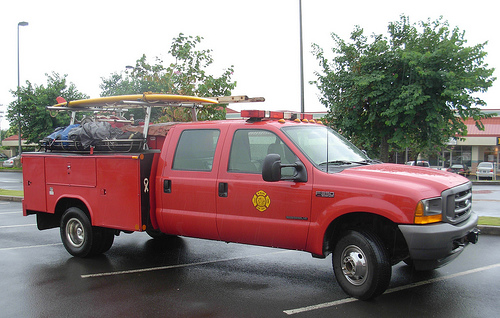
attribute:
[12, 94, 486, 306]
truck — red, parking lot, big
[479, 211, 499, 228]
strip — green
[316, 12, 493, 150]
tree — small, green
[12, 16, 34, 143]
pole — tall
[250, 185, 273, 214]
insignia — yellow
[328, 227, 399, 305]
tire — rubber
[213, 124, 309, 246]
door — red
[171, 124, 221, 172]
window — glass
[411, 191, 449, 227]
headlight — orange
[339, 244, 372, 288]
hubcap — silver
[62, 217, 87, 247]
hubcap — silver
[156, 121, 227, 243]
door — red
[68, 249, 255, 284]
line — white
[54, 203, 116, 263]
tire — back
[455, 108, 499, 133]
roof — red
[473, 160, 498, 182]
car — white